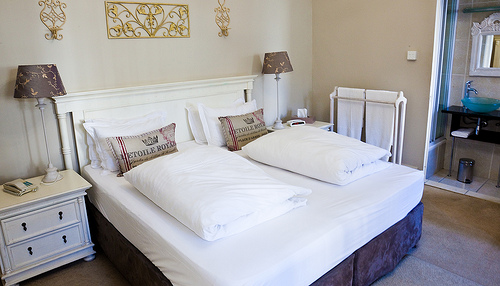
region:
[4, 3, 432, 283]
A bedroom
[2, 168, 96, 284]
A white night stand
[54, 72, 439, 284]
A large bed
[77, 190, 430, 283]
A dark colored bedskirt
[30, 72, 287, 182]
A white headboard on a bed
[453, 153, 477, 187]
A silver trashcan with a black foot pedal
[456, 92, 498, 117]
A light blue sink bowl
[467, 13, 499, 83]
A white framed mirror hanging on the wall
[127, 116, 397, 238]
White folded bedding on top of a bed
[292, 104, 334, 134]
A box of tissues on a nightstand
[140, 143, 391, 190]
two blankets on the bed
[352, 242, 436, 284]
blue bottom on the bed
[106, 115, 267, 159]
two pillows on the bed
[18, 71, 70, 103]
brown printed lamp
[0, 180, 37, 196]
telephone on the stand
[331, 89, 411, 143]
towels on the rack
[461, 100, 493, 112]
blue basin on the sink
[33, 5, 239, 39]
decorations on the wall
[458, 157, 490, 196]
waste bin under sink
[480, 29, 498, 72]
mirror on the wall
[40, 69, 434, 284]
large bed in bedroom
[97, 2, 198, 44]
gold colored decoration on wall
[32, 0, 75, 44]
pineapple shaped decoration on wall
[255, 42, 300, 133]
lamp with dark colored shade next to bed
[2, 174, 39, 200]
phone on night stand next to bed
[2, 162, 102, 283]
white two drawer-ed night stand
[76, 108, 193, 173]
stack of pillows at the head of bed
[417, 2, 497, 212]
bathroom adjacent to bedroom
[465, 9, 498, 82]
mirror on wall in bathroom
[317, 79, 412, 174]
white towels on towel rack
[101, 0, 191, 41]
gold rectangular artwork on the wall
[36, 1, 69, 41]
small gold artwork on the wall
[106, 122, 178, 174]
gray and red decorative pillow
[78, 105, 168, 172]
white pillows on the bed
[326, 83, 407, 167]
towel rack near the bed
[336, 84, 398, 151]
white towels on the rack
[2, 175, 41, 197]
telephone on the nightstand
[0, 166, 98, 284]
white nightstand near the bed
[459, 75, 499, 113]
sink and faucet in the bathroom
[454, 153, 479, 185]
trashcan in the bathroom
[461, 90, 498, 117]
Blue sink bowl in bathroom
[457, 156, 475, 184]
Metal trash can in bathroom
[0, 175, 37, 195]
Beige phone on top of white nightstand.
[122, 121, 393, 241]
Two large folded white blankets on the bed.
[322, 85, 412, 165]
White rack with two white towels on it.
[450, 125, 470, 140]
Folded white towel on black shelf in bathroom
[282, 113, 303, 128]
White alarm clock on white nightstand.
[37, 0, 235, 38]
Two gold candle holders with matching centerpiece on wall.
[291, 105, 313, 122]
Brown tissue box on top of white nightstand.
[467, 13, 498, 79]
Bathroom mirror with white frame on bathroom wall.